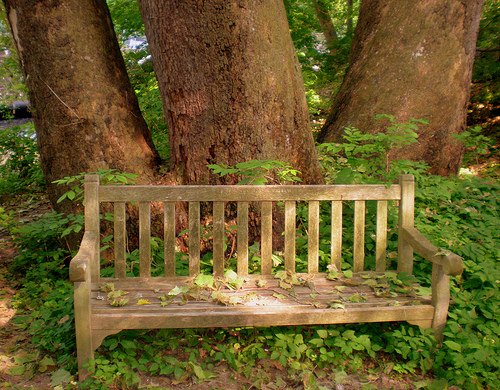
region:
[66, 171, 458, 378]
vacant wooden bench with leaves on it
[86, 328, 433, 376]
green plant growing under the bench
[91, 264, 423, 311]
leaves that have fallen on the bench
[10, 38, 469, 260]
bottom of three tree stumps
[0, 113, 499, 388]
green foliage growing all around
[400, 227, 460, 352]
arm handle of the wooden bench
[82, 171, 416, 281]
back rest of the wooden bench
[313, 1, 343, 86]
tree trunk seen in the background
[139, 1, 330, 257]
large brown tree trunk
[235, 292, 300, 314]
bright area where the sun is shining through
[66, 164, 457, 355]
Brown bench with slatted back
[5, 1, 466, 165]
Large tree trunks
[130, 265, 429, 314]
Scattered leaves on bench seat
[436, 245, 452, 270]
Fallen leaf on bench arm rest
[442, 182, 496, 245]
Green plants covering the ground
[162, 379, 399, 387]
Dirt covered ground in front of bench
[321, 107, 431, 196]
Tall plants growing behind bench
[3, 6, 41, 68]
Piece of bark missing from tree trunk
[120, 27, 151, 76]
Part of the sky visible through the trees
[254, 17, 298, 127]
Green moss growing on side of tree trunk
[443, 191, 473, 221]
green plant on ground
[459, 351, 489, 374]
green plant on ground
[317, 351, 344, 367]
green plant on ground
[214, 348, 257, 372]
green plant on ground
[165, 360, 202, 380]
green plant on ground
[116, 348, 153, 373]
green plant on ground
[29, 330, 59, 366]
green plant on ground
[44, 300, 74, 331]
green plant on ground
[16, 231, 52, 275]
green plant on ground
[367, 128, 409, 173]
green plant on ground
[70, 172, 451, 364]
The bench is in the bushes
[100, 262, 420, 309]
Brown and green leaves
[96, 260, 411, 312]
The leaves are on the bench seat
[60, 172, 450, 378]
The bench is brown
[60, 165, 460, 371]
The bench is made of wood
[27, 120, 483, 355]
Bushes around the bottom of the trees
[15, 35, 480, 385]
Bench next to trees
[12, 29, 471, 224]
There are three trees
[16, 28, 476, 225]
The tree trunks are thick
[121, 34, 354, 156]
Bushes behind the trees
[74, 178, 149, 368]
brown wooden bench covered by green leaves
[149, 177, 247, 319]
brown wooden bench covered by green leaves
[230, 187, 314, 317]
brown wooden bench covered by green leaves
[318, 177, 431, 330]
brown wooden bench covered by green leaves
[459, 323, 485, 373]
green colored ivy growing in woods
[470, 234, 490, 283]
green colored ivy growing in woods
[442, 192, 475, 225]
green colored ivy growing in woods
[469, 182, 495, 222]
green colored ivy growing in woods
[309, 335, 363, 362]
green colored ivy growing in woods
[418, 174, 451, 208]
green colored ivy growing in woods